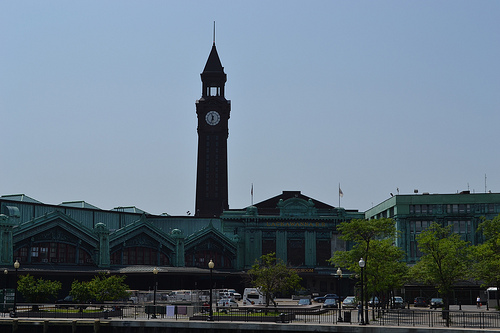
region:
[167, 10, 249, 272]
tall clock tower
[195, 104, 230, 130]
white clock in the sky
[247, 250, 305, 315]
short green tree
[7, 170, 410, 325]
green building under the clock tower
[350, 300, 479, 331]
black metal fence around the building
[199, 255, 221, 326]
black and white light post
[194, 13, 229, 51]
pointed tip of the clock tower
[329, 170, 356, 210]
flags on the rooftop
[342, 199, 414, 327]
tall healthy green trees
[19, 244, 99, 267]
windows of the building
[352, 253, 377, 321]
white globe on black pole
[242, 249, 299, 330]
green leaves on a tree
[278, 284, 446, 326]
cars parked in parking lot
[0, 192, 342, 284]
large green colored building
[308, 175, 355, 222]
flag on top of building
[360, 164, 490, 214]
silver antennaes on top of building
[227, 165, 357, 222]
two flags on roof of building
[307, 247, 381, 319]
two strett lights in parking lot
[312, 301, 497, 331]
a small black gate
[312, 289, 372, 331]
a garbage can on sidewalk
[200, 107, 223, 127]
a white clock face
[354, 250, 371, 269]
a street lamp on the post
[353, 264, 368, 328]
a metal lamp post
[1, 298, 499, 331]
a black metal railing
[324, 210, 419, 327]
a row of green trees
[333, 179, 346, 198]
a white flag on the flag pole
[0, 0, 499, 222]
a clear blue sky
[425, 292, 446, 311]
a black car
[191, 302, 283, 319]
a patch of green grass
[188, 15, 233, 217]
a large clock tower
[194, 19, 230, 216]
tall dark clock tower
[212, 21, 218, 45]
lightning rod on top of tower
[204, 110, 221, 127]
round white clock face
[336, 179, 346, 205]
flag pole on building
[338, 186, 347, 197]
flag on flag pole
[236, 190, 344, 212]
black roof of building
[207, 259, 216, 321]
tall black lamp post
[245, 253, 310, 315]
tree in front of building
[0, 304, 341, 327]
black metal fence near tree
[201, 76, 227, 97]
empty belfry on tower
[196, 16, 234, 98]
the tower of a clock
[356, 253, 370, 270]
a street light on the pole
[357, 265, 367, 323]
a black lamp post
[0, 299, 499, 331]
a small black railing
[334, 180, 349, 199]
a flag on a flag pole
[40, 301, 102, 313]
a patch of green grass